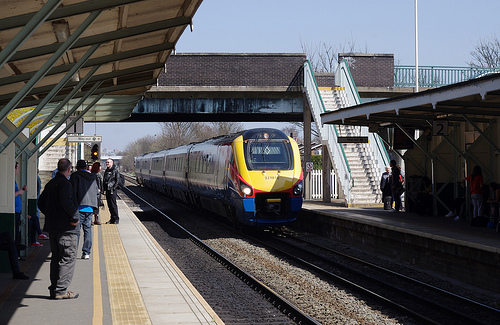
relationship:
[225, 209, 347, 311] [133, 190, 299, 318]
gravel on tracks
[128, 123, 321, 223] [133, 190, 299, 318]
train on tracks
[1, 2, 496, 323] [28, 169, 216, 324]
station has platform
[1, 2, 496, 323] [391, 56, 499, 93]
station has guardrail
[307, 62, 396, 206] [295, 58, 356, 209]
stairs with wall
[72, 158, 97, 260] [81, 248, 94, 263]
man wearing sneakers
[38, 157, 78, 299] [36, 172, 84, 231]
people wearing jacket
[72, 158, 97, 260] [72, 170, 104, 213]
man wearing jacket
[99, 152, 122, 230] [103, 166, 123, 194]
man wearing jacket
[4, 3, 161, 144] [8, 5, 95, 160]
roof support beams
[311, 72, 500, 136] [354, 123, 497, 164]
roof support beams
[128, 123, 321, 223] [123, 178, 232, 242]
train has shadow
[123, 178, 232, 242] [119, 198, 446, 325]
shadow on ground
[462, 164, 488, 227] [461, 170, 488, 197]
shirt wearing shirt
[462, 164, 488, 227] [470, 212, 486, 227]
shirt wearing shoes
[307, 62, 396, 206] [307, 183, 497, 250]
stairs to platform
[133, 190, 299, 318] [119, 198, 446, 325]
rails on ground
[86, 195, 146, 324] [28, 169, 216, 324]
line across platform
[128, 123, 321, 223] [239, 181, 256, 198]
train with headlight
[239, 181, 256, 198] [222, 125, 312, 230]
headlight on front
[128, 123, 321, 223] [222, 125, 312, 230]
train has front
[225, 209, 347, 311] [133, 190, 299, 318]
rocks near track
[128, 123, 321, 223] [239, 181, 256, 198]
train with light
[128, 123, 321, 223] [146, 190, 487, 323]
train on track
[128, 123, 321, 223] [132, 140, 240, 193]
train has side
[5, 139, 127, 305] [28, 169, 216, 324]
people on sidewalk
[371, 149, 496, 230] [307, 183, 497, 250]
people on sidewalk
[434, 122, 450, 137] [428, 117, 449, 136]
2 on sign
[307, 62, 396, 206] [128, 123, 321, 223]
stairs near train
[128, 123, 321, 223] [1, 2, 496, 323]
train at station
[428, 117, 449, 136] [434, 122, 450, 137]
sign with 2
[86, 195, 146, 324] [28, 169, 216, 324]
lines on sidewalk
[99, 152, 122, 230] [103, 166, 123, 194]
person wearing jacket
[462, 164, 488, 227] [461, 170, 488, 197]
woman wearing top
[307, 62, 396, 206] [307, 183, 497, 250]
stairs behind platform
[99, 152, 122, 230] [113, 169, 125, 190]
man holding backpack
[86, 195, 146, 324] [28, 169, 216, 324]
paint near platform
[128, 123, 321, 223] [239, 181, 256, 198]
train has headlight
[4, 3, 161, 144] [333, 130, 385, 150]
roof has sign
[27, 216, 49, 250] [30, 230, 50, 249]
person wearing shoes